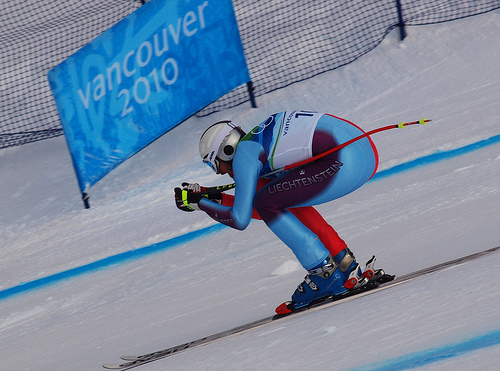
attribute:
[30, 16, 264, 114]
sign — blue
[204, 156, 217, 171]
lenses — blue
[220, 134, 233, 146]
strap — white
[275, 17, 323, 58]
fence — blue checked, brown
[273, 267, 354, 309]
snowboot — blue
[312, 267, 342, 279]
buckles — silver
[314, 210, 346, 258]
pant leg — red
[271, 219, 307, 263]
pant leg — blue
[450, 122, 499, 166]
line — blue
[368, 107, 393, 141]
stick — red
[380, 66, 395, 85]
snow — white